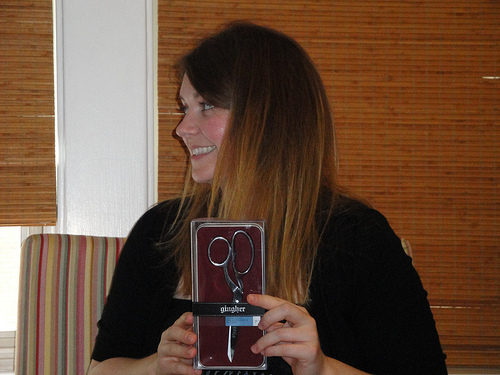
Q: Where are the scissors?
A: In the woman's hand.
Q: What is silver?
A: The scissors.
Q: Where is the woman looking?
A: To the right.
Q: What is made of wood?
A: The shades.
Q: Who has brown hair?
A: The woman.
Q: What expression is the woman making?
A: Smiling.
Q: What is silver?
A: The scissors.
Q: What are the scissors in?
A: The case.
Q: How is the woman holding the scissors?
A: In her hand.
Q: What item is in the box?
A: Scissor.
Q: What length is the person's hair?
A: Long.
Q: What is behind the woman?
A: Back of chair.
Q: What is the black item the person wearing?
A: Shirt.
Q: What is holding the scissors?
A: Hands.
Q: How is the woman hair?
A: Long.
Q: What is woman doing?
A: Smiling.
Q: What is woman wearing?
A: Black shirt.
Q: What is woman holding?
A: Scissors.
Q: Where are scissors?
A: Case.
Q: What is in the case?
A: Scissors.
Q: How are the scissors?
A: Sharp.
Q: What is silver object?
A: Scissors.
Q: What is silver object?
A: Scissor.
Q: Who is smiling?
A: The woman.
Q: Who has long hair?
A: A woman.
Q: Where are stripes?
A: On a chair.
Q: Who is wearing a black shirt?
A: Woman smiling.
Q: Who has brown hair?
A: The lady.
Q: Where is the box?
A: In woman's hands.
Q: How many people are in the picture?
A: 1.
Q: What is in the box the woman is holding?
A: Scissors.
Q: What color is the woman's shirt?
A: Black.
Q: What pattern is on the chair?
A: Stripes.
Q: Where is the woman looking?
A: To the left.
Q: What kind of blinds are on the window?
A: Bamboo.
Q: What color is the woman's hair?
A: Brown.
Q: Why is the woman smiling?
A: Happy.